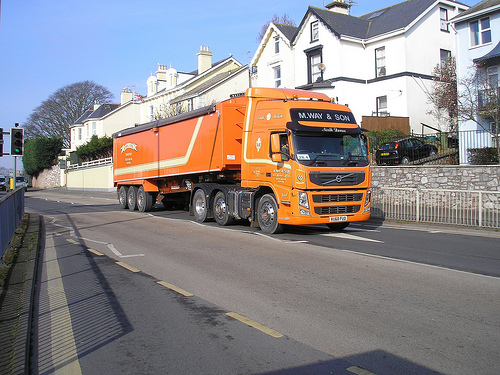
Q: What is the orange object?
A: A truck.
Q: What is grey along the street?
A: A fence.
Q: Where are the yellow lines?
A: On the street.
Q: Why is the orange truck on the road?
A: Driving.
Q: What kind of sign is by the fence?
A: A traffic sign.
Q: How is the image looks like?
A: Good.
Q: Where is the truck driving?
A: On street.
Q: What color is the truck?
A: Orange.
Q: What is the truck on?
A: The street.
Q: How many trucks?
A: 1.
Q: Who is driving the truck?
A: Driver.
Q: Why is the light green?
A: To go.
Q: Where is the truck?
A: In front of the houses.